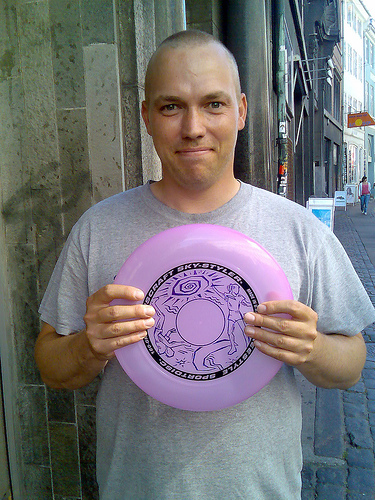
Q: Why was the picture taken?
A: To capture the man.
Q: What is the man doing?
A: Holding a frisbee.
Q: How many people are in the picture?
A: One.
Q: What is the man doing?
A: Smiling.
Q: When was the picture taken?
A: During the day.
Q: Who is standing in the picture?
A: A man.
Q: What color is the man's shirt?
A: Heather gray.